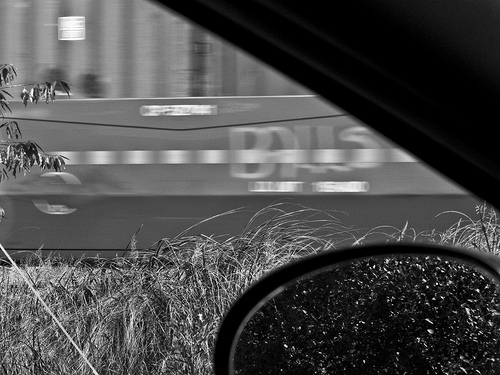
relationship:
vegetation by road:
[1, 202, 500, 374] [2, 196, 497, 256]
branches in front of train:
[0, 118, 70, 172] [2, 93, 492, 263]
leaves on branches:
[61, 259, 232, 345] [21, 53, 115, 150]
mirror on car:
[211, 239, 498, 371] [148, 1, 498, 213]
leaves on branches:
[3, 61, 70, 181] [2, 58, 69, 180]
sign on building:
[54, 13, 87, 42] [2, 4, 311, 94]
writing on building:
[226, 123, 386, 180] [2, 99, 482, 262]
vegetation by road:
[1, 202, 500, 374] [44, 95, 389, 244]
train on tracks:
[0, 87, 438, 349] [21, 256, 256, 291]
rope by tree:
[10, 247, 118, 374] [2, 75, 69, 262]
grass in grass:
[0, 195, 499, 372] [23, 252, 182, 352]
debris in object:
[282, 250, 437, 331] [197, 234, 496, 366]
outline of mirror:
[186, 225, 493, 372] [236, 253, 497, 368]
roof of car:
[171, 7, 499, 218] [168, 4, 497, 185]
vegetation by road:
[1, 202, 498, 374] [19, 114, 483, 292]